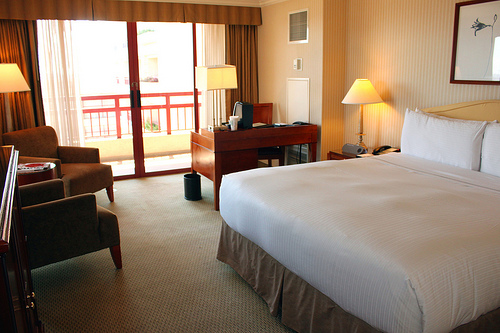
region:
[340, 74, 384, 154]
Lamp on the table.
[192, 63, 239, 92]
Square lamp shade.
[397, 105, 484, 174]
White pillow on the bed.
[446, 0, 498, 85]
Picture on the wall.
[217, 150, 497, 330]
White bed covering.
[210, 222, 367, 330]
Tan bed skirt on the bed.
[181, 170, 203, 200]
Black trash can in the room.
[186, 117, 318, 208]
Brown desk in the background.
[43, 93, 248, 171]
Balcony in the background.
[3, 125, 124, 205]
Brown chair by the door.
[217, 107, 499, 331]
a wide and large bed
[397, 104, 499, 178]
a set of white pillow cases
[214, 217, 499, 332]
a large brown sheet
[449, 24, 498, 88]
a picture with brown frame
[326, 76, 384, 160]
a lamp setting beside bed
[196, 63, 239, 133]
a lamp with a square shade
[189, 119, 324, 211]
a brown wooden desk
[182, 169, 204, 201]
a small trash can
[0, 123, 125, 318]
two brown chairs in bedroom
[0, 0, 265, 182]
two large window curtains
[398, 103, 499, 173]
pillows on the bed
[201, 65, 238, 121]
one of several lamps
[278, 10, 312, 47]
vent on the wall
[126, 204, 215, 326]
tan carpet on the floor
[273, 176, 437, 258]
white sheet on bed top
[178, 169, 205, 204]
receptacle for the trash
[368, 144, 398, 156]
phone on the desk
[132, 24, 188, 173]
glass door to terrace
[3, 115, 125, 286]
two chairs across from bed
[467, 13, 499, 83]
image on the picture on wall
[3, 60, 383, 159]
three lamps in the bedroom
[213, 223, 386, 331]
bed skirt around the bed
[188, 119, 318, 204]
desk in front of sliding glass doors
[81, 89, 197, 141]
red railing on balcony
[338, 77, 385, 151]
lamp by the bedside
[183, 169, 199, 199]
black trashcan beside desk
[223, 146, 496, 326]
white sheets on the bed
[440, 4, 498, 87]
picture hung above the bed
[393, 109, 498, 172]
two white pillows on the bed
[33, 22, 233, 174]
two sliding glass doors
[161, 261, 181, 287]
carpet on the floor.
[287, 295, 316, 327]
bed skirt on the bed.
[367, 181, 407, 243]
comforter on the bed.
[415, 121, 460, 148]
pillow on the bed.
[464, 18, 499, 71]
portrait above the bed.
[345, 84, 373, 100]
lamp shade near the bed.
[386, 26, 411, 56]
wallpaper on the wall.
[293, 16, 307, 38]
vent on the wall.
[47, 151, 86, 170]
chair in the corner.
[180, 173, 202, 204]
trash can near the desk.